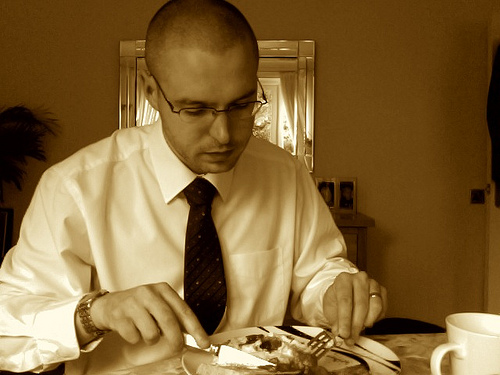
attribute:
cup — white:
[429, 315, 482, 373]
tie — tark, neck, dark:
[184, 178, 228, 334]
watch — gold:
[78, 289, 109, 340]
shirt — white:
[2, 120, 367, 375]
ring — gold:
[370, 293, 383, 299]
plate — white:
[182, 326, 401, 374]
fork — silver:
[302, 327, 341, 360]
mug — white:
[431, 311, 497, 375]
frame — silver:
[119, 38, 316, 173]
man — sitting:
[2, 2, 389, 350]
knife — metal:
[182, 334, 276, 371]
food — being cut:
[215, 334, 336, 375]